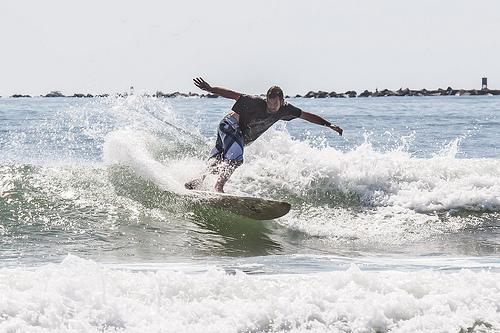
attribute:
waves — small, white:
[85, 98, 498, 211]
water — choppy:
[1, 97, 500, 333]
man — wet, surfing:
[184, 76, 342, 193]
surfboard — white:
[186, 189, 293, 220]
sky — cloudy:
[0, 0, 498, 96]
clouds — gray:
[1, 0, 498, 96]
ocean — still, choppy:
[0, 98, 499, 333]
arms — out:
[192, 76, 343, 136]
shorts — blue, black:
[207, 115, 245, 162]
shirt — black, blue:
[231, 93, 301, 146]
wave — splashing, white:
[103, 94, 375, 200]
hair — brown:
[266, 86, 285, 100]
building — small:
[481, 76, 488, 90]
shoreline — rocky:
[0, 88, 499, 98]